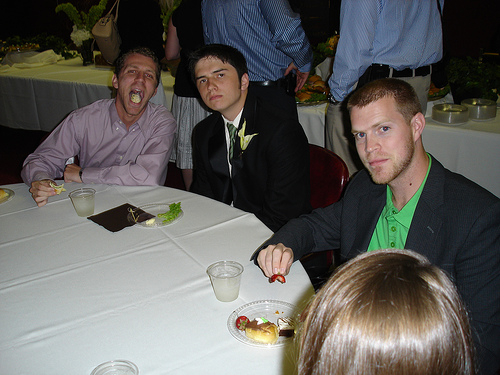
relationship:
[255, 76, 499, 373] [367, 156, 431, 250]
guy wearing shirt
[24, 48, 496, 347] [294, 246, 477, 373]
boys have a female companion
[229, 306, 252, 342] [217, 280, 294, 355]
strawberry on plate